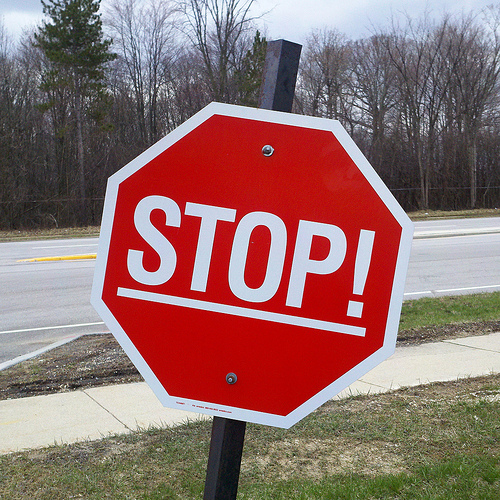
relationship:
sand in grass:
[248, 434, 407, 485] [2, 290, 498, 499]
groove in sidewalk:
[78, 388, 134, 432] [2, 331, 500, 454]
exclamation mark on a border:
[347, 229, 378, 320] [89, 101, 414, 429]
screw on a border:
[263, 146, 275, 156] [89, 101, 414, 429]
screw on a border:
[226, 374, 237, 385] [89, 101, 414, 429]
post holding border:
[258, 39, 303, 112] [89, 101, 414, 429]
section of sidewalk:
[344, 342, 499, 391] [2, 331, 500, 454]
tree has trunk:
[34, 1, 105, 214] [68, 82, 90, 202]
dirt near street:
[3, 331, 145, 400] [1, 217, 500, 375]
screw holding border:
[263, 146, 275, 156] [89, 101, 414, 429]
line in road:
[19, 225, 498, 265] [1, 217, 500, 375]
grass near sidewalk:
[2, 290, 498, 499] [2, 331, 500, 454]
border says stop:
[89, 101, 414, 429] [126, 195, 349, 309]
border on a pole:
[89, 101, 414, 429] [205, 416, 248, 498]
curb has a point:
[3, 331, 111, 379] [76, 327, 90, 346]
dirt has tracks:
[3, 331, 145, 400] [0, 370, 141, 398]